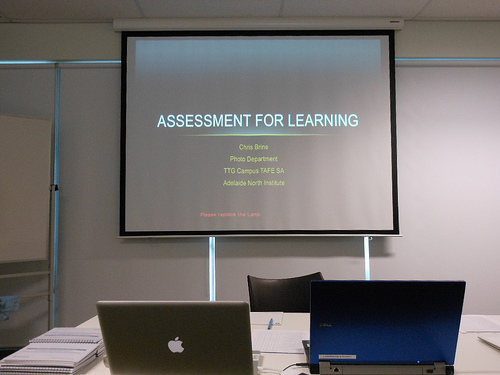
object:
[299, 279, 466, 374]
open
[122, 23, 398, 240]
screen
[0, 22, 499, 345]
wall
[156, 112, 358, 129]
writing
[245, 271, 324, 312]
chair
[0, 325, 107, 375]
book